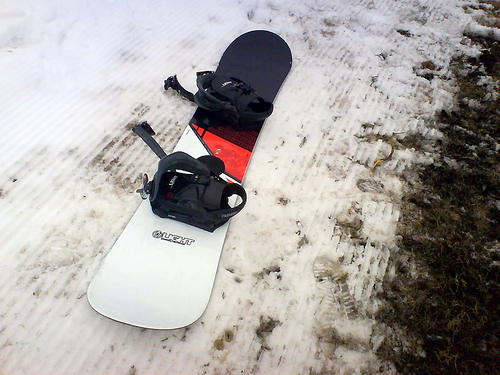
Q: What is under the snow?
A: Grass.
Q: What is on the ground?
A: Snow.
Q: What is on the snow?
A: Snowboard.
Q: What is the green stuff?
A: Grass.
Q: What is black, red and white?
A: Snowboard.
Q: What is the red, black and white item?
A: Snowboard.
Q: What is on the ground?
A: Snow.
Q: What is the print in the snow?
A: Footprint.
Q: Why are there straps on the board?
A: Foot straps.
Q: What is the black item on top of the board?
A: Boot straps.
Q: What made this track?
A: Tire tread.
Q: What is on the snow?
A: Dirt, tracks, footprints.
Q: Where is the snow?
A: On the ground.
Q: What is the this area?
A: White part of snowboard.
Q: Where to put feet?
A: Places.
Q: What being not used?
A: Snowboard.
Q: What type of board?
A: Red, white and black.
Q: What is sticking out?
A: The grass.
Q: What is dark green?
A: The grass.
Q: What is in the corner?
A: A lot of snow.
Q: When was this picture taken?
A: The winter.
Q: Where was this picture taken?
A: In yard.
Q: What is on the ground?
A: Snow.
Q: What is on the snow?
A: Snowboard.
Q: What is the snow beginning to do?
A: Melt.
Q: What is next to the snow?
A: Mud.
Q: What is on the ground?
A: Snowboard.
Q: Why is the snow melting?
A: The temperature.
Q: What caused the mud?
A: Melting snow.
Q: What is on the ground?
A: Snow.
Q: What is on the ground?
A: A snowboard.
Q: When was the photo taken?
A: Daytime.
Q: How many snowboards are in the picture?
A: One.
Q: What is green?
A: Grass.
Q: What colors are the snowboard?
A: White, red and black.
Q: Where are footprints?
A: On the snow.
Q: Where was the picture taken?
A: Ski slope.